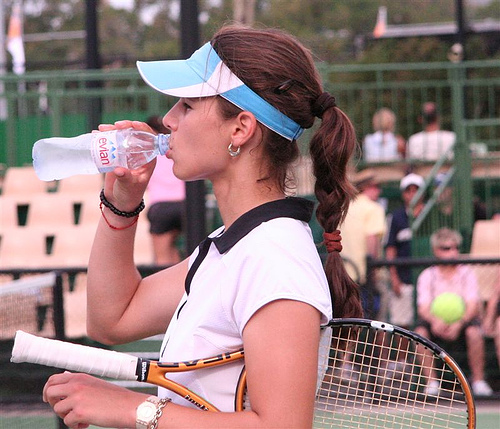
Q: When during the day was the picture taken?
A: Daytime.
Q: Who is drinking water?
A: A woman.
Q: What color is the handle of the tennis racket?
A: White.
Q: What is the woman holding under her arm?
A: A tennis racket.